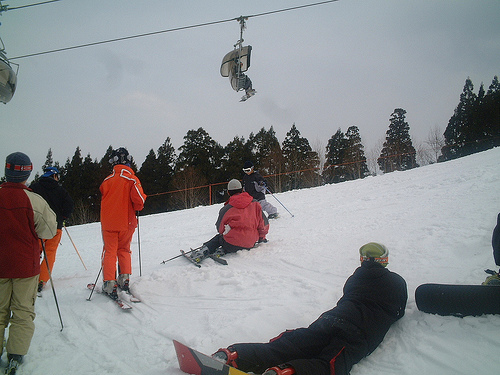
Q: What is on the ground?
A: Snow.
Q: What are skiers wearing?
A: Jacket and jeans.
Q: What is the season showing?
A: Winter.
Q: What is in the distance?
A: Trees.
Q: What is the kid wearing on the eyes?
A: Goggles.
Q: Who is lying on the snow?
A: A boy.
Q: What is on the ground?
A: Snow.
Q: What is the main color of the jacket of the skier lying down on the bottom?
A: Black.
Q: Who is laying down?
A: Two snowboarders and a skier.